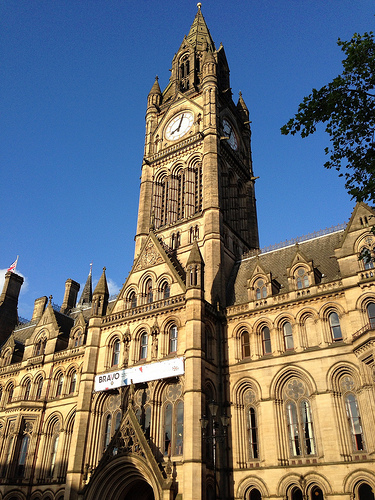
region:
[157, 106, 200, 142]
Clock on top of building.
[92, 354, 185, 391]
"BRAVO" sign hangs over building's entrance.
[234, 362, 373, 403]
Large arch shaped windows on front of building.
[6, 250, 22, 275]
Red and white flags is visible on top of building.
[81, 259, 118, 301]
Two steeples are on the left side of the building.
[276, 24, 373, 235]
Tree is located on the right side of the building.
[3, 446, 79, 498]
Shadows of something can be seen on the left side.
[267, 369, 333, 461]
White curtains are visible in the window.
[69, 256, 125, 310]
White can be seen in the background.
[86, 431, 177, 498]
Entrance of building is darkened by shadows.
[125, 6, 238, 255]
a very tall tower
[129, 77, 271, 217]
the tower has a clock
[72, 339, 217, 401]
the white sign on the building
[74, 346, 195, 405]
the sign is white with black letters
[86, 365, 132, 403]
the black letters say bravo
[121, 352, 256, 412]
red and blue triangles on the sign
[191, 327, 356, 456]
building is made of stone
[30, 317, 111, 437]
the building is brown stone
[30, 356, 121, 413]
there are many windows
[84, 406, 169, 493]
large triangle over door opening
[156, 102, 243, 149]
two clock faces on tower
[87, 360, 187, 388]
bravo banner hanging above entry way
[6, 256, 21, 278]
flag flying on top of chimney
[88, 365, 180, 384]
white banner with colored text hanging on building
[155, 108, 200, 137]
clock face facing left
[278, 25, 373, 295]
branches of tree with green leaves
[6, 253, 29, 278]
white and red flag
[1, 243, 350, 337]
roof of the building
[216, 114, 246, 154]
clock face facing right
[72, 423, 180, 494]
entry way to building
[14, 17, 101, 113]
the clear blue sky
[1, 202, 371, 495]
the tan building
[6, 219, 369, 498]
the building is old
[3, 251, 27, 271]
the flag on the building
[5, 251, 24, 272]
the flag waving in the wind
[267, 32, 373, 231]
the branches with leaves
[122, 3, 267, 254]
the tower on the building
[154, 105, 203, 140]
the clock on the tower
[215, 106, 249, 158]
the clock on the twoer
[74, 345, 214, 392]
the sign on the building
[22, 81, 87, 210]
Sky is blue color.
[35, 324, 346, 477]
wall is brown color.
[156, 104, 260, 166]
Two face of clock is seen in the tower.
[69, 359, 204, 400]
Board is white color.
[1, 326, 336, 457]
windows are in the walls of the building.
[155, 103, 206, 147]
Clock is white and black color.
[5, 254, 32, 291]
Flag is in the top of the tower.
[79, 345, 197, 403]
Board is attached to building wall.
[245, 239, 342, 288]
Roof is brown color.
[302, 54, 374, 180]
Leaves are green color.